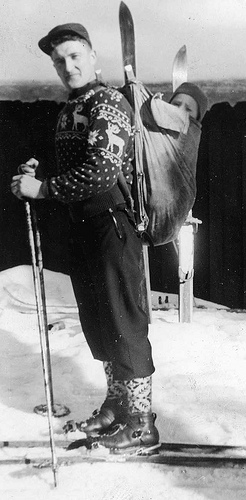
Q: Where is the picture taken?
A: Ski slope.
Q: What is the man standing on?
A: Skis.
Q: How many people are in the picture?
A: Two.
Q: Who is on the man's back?
A: A child.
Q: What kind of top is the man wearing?
A: Sweater.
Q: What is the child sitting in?
A: Backpack.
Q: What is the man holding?
A: Poles.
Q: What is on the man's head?
A: A hat.